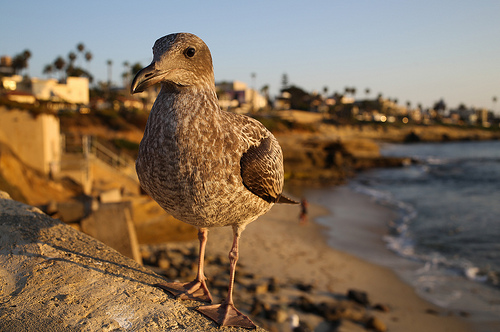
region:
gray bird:
[109, 26, 317, 293]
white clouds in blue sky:
[84, 7, 125, 41]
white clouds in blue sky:
[254, 17, 281, 52]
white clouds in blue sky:
[311, 14, 332, 65]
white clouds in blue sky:
[411, 21, 449, 76]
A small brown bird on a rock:
[130, 22, 325, 317]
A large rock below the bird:
[45, 239, 167, 329]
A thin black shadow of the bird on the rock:
[0, 233, 179, 290]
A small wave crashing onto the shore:
[359, 185, 474, 282]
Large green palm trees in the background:
[47, 34, 127, 80]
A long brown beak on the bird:
[130, 63, 178, 100]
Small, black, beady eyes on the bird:
[150, 42, 206, 63]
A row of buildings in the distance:
[225, 71, 407, 126]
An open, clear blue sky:
[284, 16, 421, 76]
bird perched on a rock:
[124, 18, 309, 323]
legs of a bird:
[174, 217, 262, 330]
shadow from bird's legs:
[40, 233, 149, 288]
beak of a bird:
[110, 60, 165, 93]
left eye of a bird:
[176, 40, 201, 61]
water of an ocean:
[363, 168, 487, 273]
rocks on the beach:
[243, 272, 383, 328]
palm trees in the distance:
[56, 43, 99, 66]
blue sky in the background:
[277, 15, 469, 64]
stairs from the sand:
[79, 129, 144, 184]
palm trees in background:
[41, 34, 131, 80]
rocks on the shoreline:
[321, 152, 426, 172]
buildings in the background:
[209, 83, 491, 130]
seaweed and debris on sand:
[146, 237, 395, 331]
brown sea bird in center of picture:
[127, 24, 297, 327]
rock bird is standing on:
[9, 227, 263, 325]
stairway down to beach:
[81, 132, 131, 174]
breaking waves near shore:
[350, 171, 495, 308]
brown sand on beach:
[221, 190, 493, 329]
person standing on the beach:
[298, 191, 315, 231]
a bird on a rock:
[131, 27, 283, 312]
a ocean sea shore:
[344, 120, 495, 315]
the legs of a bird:
[172, 225, 257, 317]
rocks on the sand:
[302, 277, 384, 319]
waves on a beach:
[374, 163, 419, 287]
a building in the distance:
[30, 70, 85, 95]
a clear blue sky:
[250, 4, 485, 84]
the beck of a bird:
[132, 57, 163, 107]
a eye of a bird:
[182, 35, 197, 75]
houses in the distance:
[292, 90, 493, 124]